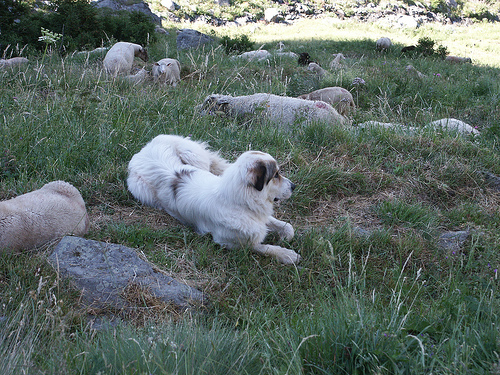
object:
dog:
[127, 134, 301, 265]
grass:
[0, 19, 500, 375]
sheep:
[0, 180, 92, 253]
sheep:
[201, 93, 352, 138]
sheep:
[103, 41, 150, 78]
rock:
[45, 235, 211, 330]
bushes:
[1, 0, 156, 58]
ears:
[246, 159, 267, 191]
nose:
[291, 182, 297, 192]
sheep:
[297, 52, 322, 67]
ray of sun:
[144, 0, 499, 69]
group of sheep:
[0, 37, 481, 138]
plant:
[37, 27, 64, 81]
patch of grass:
[307, 190, 426, 244]